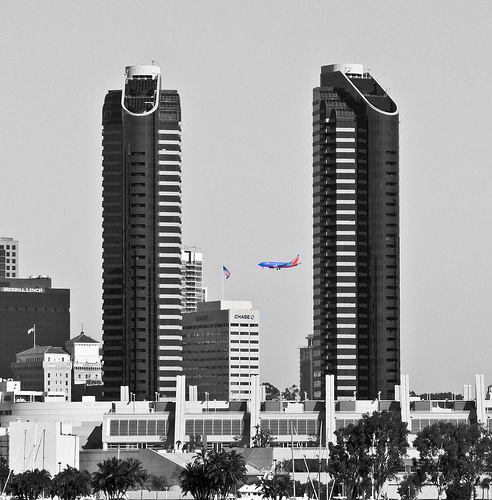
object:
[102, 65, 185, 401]
tower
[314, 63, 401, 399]
tower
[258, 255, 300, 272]
airplane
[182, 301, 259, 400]
building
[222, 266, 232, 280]
flag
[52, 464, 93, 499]
tree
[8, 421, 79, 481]
building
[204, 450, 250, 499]
tree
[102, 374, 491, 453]
building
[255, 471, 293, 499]
tree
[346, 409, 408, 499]
tree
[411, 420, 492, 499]
tree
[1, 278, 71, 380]
building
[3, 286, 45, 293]
label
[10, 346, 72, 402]
building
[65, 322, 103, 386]
building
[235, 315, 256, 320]
logo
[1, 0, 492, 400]
sky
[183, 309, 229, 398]
side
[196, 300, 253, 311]
part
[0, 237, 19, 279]
building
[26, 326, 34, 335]
flag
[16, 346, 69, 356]
roof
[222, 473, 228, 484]
leaves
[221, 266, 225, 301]
pole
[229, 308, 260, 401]
edge